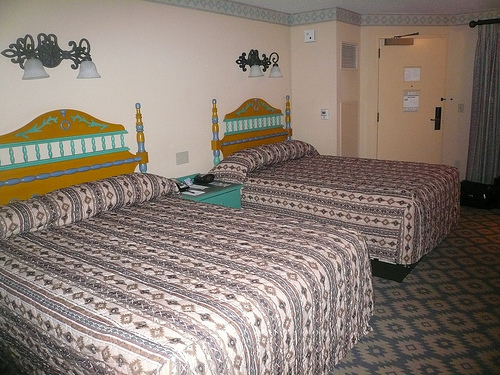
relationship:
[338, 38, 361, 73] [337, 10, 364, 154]
vent in wall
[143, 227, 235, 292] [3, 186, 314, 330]
comforter on bed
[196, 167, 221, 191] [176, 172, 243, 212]
clock on desk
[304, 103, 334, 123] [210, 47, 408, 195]
thermostat on wall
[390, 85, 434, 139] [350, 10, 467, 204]
notice on door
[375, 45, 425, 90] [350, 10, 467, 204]
notice on door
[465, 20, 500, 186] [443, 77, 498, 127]
curtains covering window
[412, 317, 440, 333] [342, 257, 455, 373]
pattern on floor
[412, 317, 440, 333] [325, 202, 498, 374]
pattern on floor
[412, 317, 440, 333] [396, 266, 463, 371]
pattern on floor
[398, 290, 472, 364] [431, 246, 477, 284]
pattern on floor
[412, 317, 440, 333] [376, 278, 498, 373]
pattern on floor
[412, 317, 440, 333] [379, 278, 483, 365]
pattern on floor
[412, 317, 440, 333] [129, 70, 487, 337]
pattern on floor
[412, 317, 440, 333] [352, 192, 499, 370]
pattern on floor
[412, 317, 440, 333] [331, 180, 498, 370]
pattern on floor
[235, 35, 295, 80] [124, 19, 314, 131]
lights on wall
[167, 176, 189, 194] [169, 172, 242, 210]
phone on desk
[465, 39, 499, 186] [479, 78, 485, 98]
curtains hanging in front of window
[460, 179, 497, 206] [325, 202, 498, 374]
suitcase on floor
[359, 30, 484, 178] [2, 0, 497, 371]
door to room